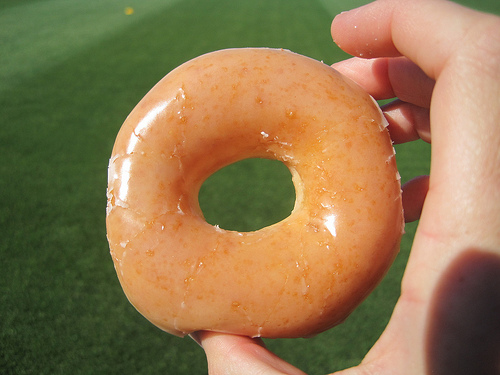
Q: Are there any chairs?
A: No, there are no chairs.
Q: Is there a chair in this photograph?
A: No, there are no chairs.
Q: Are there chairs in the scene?
A: No, there are no chairs.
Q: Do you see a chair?
A: No, there are no chairs.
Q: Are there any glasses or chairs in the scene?
A: No, there are no chairs or glasses.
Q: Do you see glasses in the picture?
A: No, there are no glasses.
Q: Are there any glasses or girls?
A: No, there are no glasses or girls.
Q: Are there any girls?
A: No, there are no girls.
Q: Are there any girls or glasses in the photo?
A: No, there are no girls or glasses.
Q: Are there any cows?
A: Yes, there is a cow.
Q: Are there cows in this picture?
A: Yes, there is a cow.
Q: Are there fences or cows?
A: Yes, there is a cow.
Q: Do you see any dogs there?
A: No, there are no dogs.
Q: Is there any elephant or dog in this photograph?
A: No, there are no dogs or elephants.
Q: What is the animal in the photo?
A: The animal is a cow.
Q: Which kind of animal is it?
A: The animal is a cow.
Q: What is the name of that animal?
A: This is a cow.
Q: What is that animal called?
A: This is a cow.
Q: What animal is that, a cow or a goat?
A: This is a cow.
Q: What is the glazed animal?
A: The animal is a cow.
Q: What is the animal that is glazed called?
A: The animal is a cow.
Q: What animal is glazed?
A: The animal is a cow.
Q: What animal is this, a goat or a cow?
A: This is a cow.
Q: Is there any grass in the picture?
A: Yes, there is grass.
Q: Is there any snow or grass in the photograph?
A: Yes, there is grass.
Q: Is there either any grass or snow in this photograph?
A: Yes, there is grass.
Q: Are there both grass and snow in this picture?
A: No, there is grass but no snow.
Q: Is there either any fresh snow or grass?
A: Yes, there is fresh grass.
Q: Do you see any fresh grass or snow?
A: Yes, there is fresh grass.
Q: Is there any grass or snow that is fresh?
A: Yes, the grass is fresh.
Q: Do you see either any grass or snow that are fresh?
A: Yes, the grass is fresh.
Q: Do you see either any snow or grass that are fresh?
A: Yes, the grass is fresh.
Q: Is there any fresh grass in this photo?
A: Yes, there is fresh grass.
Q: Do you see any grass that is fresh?
A: Yes, there is fresh grass.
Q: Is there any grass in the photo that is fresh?
A: Yes, there is grass that is fresh.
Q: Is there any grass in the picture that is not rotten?
A: Yes, there is fresh grass.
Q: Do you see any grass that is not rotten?
A: Yes, there is fresh grass.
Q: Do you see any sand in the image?
A: No, there is no sand.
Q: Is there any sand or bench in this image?
A: No, there are no sand or benches.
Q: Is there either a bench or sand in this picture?
A: No, there are no sand or benches.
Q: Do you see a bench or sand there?
A: No, there are no sand or benches.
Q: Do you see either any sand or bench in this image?
A: No, there are no sand or benches.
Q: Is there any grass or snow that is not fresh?
A: No, there is grass but it is fresh.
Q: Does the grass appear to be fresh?
A: Yes, the grass is fresh.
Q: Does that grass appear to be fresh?
A: Yes, the grass is fresh.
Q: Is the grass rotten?
A: No, the grass is fresh.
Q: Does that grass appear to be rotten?
A: No, the grass is fresh.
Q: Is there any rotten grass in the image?
A: No, there is grass but it is fresh.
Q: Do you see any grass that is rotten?
A: No, there is grass but it is fresh.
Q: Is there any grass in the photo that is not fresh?
A: No, there is grass but it is fresh.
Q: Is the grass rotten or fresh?
A: The grass is fresh.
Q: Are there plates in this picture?
A: No, there are no plates.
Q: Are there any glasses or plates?
A: No, there are no plates or glasses.